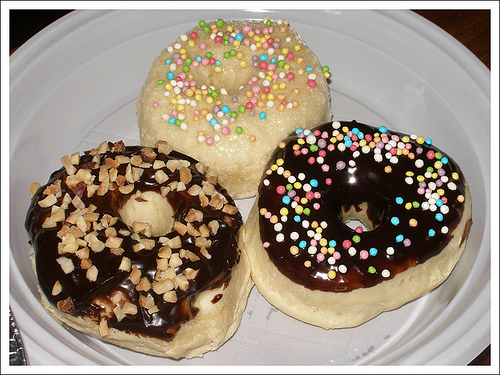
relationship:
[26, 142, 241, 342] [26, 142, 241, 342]
chocolate covered in chocolate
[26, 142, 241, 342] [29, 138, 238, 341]
chocolate covered in nuts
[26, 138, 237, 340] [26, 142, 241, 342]
peanuts in chocolate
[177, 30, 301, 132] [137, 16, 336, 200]
sprinkles on donut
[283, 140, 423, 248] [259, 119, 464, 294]
sprinkles on chocolate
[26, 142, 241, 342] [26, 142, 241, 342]
chocolate smeared on a chocolate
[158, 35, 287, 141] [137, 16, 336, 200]
glaze on a donut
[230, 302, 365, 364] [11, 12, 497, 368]
pattern on bottom of bowl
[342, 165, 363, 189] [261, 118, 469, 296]
light reflected on frosting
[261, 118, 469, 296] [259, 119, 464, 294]
frosting on chocolate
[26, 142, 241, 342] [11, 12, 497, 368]
chocolate on bowl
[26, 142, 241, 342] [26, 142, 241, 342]
chocolate with chocolate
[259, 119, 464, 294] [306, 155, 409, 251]
chocolate with chocolate frosting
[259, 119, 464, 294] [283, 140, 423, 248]
chocolate has sprinkles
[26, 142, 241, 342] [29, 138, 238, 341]
chocolate with nuts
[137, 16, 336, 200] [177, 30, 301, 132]
donut with sprinkles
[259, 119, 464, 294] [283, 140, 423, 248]
chocolate with sprinkles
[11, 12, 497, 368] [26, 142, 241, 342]
bowl holding chocolate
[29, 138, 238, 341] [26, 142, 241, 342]
nuts on top of chocolate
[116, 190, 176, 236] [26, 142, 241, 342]
hole in center of chocolate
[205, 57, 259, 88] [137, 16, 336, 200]
hole in center of donut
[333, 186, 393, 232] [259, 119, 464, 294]
hole in center of chocolate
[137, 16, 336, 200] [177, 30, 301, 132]
donut has sprinkles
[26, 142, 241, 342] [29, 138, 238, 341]
chocolate has nuts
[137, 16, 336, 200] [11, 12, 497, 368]
donut on bowl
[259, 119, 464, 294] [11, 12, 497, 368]
chocolate on bowl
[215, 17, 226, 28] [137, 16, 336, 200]
sprinkle on donut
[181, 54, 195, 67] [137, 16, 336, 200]
sprinkle on donut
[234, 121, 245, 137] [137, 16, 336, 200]
sprinkle on donut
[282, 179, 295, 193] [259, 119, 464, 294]
sprinkle on chocolate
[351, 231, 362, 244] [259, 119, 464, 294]
sprinkle on chocolate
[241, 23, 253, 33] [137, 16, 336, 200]
sprinkle on donut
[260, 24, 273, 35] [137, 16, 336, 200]
sprinkle on donut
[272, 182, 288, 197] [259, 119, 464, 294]
sprinkle on chocolate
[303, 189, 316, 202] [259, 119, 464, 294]
sprinkle on chocolate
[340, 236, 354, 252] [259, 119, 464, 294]
sprinkle on chocolate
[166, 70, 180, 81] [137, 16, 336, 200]
sprinkle on donut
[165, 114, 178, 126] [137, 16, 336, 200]
sprinkle on donut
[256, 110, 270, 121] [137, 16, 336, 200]
sprinkle on donut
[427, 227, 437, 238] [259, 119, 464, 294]
sprinkle on chocolate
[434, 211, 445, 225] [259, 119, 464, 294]
sprinkle on chocolate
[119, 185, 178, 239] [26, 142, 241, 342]
middle of chocolate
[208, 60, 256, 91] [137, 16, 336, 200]
middle of donut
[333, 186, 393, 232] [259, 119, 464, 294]
hole of chocolate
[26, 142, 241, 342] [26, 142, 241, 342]
chocolate on chocolate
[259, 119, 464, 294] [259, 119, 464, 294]
chocolate on chocolate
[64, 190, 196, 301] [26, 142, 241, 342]
walnuts on top of chocolate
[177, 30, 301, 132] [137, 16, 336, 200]
sprinkles on top of donut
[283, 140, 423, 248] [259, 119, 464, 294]
sprinkles on top of chocolate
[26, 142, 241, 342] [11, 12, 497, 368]
chocolate on a bowl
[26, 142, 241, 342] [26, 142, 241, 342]
chocolate on top of chocolate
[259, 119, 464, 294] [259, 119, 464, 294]
chocolate on top of chocolate